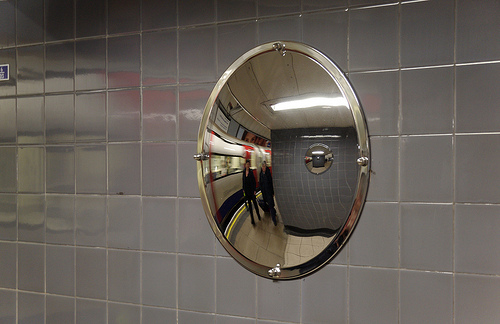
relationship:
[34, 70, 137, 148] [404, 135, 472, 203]
wall covered tiles